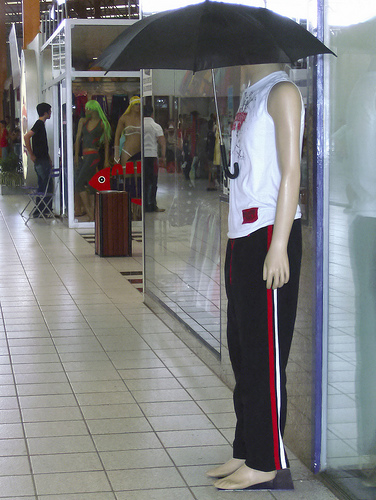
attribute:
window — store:
[43, 80, 64, 216]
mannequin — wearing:
[74, 98, 108, 219]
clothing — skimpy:
[69, 117, 149, 200]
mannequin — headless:
[204, 16, 308, 492]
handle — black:
[222, 150, 240, 179]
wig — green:
[84, 100, 113, 141]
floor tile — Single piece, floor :
[73, 391, 136, 404]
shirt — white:
[217, 77, 319, 242]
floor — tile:
[1, 187, 340, 497]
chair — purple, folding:
[20, 165, 58, 221]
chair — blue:
[19, 169, 59, 229]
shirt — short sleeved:
[227, 69, 304, 238]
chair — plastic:
[22, 165, 61, 223]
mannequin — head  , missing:
[206, 60, 307, 492]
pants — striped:
[224, 215, 302, 470]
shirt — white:
[222, 99, 278, 196]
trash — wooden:
[74, 156, 181, 292]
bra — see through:
[123, 125, 141, 136]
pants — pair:
[212, 218, 341, 491]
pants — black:
[193, 286, 295, 432]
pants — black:
[203, 210, 301, 498]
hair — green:
[72, 90, 112, 161]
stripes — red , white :
[264, 222, 286, 476]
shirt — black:
[24, 114, 54, 162]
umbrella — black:
[95, 3, 342, 180]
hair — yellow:
[115, 90, 147, 115]